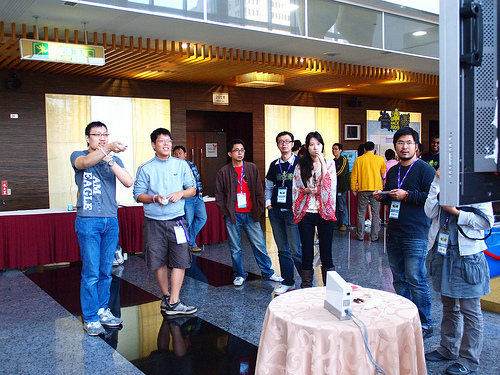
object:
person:
[372, 126, 440, 339]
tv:
[440, 0, 500, 208]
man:
[71, 121, 133, 336]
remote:
[118, 143, 129, 149]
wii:
[324, 271, 353, 321]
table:
[254, 285, 427, 375]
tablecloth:
[352, 285, 426, 374]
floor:
[0, 241, 282, 374]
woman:
[292, 131, 338, 288]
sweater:
[292, 154, 337, 225]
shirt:
[71, 150, 125, 218]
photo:
[0, 0, 499, 374]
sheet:
[352, 290, 376, 312]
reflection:
[53, 301, 164, 373]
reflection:
[81, 324, 117, 374]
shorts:
[142, 214, 191, 271]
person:
[133, 128, 197, 315]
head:
[85, 121, 108, 150]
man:
[214, 139, 285, 287]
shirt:
[234, 165, 253, 213]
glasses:
[85, 132, 109, 137]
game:
[118, 144, 128, 149]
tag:
[174, 225, 187, 244]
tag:
[277, 187, 288, 203]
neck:
[281, 151, 293, 160]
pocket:
[225, 210, 260, 224]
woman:
[424, 166, 495, 374]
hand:
[316, 151, 325, 162]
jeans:
[74, 215, 119, 323]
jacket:
[215, 161, 265, 225]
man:
[263, 131, 302, 296]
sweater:
[264, 152, 298, 209]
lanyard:
[279, 154, 296, 187]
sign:
[19, 38, 106, 66]